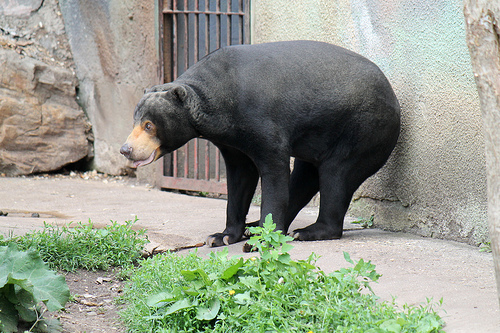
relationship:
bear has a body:
[122, 38, 403, 253] [251, 75, 332, 121]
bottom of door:
[164, 176, 220, 198] [156, 7, 253, 41]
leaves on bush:
[250, 209, 292, 254] [197, 273, 315, 316]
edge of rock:
[35, 210, 41, 214] [147, 225, 200, 255]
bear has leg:
[122, 38, 403, 253] [203, 167, 256, 252]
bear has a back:
[122, 38, 403, 253] [216, 57, 319, 90]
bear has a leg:
[122, 38, 403, 253] [203, 167, 256, 252]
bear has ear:
[122, 38, 403, 253] [176, 83, 191, 101]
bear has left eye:
[122, 38, 403, 253] [144, 117, 159, 133]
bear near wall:
[122, 38, 403, 253] [373, 20, 459, 58]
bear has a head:
[122, 38, 403, 253] [118, 78, 210, 175]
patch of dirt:
[80, 277, 117, 301] [65, 314, 105, 332]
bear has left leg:
[122, 38, 403, 253] [254, 174, 289, 234]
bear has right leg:
[122, 38, 403, 253] [203, 167, 256, 252]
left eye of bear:
[144, 117, 159, 133] [122, 38, 403, 253]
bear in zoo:
[122, 38, 403, 253] [7, 5, 497, 332]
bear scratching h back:
[122, 38, 403, 253] [216, 57, 319, 90]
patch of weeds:
[80, 277, 117, 301] [15, 251, 78, 320]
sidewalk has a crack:
[57, 194, 135, 215] [174, 239, 197, 257]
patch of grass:
[80, 277, 117, 301] [48, 231, 135, 277]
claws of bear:
[207, 234, 230, 247] [122, 38, 403, 253]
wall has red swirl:
[373, 20, 459, 58] [98, 39, 123, 85]